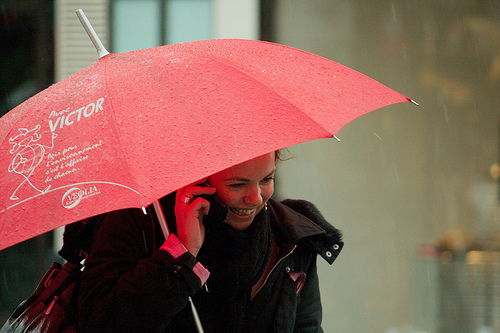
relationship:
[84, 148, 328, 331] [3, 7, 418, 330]
woman holding umbrella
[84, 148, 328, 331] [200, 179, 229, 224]
woman on phone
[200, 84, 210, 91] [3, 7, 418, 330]
rain drop on top of umbrella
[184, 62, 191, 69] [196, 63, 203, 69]
rain drop next to rain drop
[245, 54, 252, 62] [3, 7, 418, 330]
rain drop on top of umbrella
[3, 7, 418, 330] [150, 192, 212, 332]
umbrella has handle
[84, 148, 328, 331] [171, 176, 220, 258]
woman has hand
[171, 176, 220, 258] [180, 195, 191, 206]
hand has ring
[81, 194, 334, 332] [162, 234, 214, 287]
jacket has cuff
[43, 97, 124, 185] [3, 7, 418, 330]
lettering on umbrella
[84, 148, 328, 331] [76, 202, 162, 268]
woman has shoulder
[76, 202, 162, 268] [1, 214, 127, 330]
shoulder has handbag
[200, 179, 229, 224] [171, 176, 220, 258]
phone in hand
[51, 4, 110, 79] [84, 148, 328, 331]
shutter behind woman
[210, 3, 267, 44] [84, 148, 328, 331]
shutter behind woman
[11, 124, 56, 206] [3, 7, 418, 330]
logo on umbrella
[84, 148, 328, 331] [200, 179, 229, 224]
woman using phone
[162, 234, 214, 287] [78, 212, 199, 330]
cuff on sleeve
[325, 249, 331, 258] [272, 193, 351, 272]
snap on hood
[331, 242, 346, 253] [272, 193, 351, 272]
snap on hood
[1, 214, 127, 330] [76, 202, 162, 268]
handbag hanging on shoulder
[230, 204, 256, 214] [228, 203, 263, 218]
teeth in mouth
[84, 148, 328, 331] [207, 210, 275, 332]
woman wears scarf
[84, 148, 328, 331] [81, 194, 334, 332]
woman wears jacket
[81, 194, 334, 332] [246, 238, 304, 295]
jacket has zipper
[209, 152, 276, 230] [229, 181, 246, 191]
face has eye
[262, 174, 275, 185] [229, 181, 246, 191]
eye next ti eye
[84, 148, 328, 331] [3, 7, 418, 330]
woman under umbrella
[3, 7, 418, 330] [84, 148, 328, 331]
umbrella held by woman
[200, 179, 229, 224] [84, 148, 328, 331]
phone held by woman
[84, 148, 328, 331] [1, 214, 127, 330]
woman carrying handbag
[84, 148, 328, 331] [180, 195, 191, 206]
woman has ring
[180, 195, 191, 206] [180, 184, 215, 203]
ring on finger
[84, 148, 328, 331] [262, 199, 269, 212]
woman has earring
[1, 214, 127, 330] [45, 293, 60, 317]
handbag has zipper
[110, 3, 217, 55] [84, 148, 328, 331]
window behind woman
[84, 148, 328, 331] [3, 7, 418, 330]
woman with umbrella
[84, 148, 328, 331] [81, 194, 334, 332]
woman in jacket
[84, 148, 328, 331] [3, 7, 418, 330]
woman carrying umbrella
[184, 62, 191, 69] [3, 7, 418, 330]
rain drop on umbrella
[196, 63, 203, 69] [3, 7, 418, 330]
rain drop on umbrella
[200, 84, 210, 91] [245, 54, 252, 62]
rain drop next to rain drop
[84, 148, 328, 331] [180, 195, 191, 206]
woman wearing ring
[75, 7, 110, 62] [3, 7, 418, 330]
top on umbrella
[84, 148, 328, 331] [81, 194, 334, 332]
woman wearing jacket